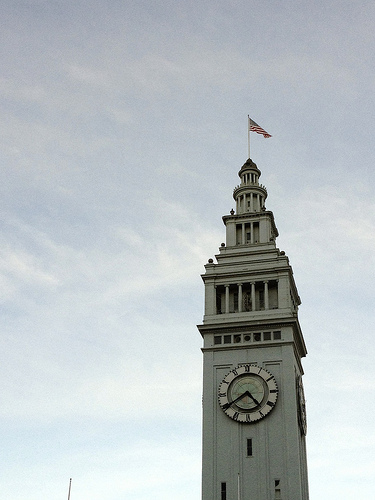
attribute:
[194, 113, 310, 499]
tower — white, tall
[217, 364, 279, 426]
clock — round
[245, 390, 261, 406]
hand — black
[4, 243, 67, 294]
cloud — white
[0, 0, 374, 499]
sky — blue, cloudy